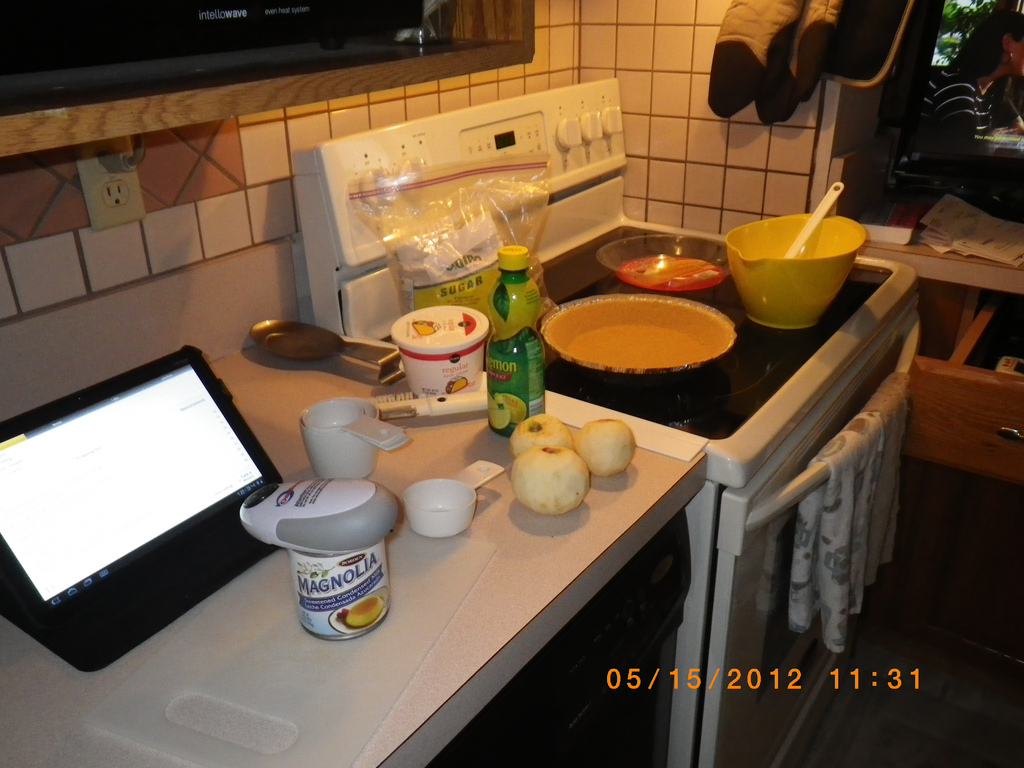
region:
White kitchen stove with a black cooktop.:
[286, 71, 917, 764]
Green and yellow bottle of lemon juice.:
[486, 242, 548, 440]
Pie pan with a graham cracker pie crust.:
[536, 286, 739, 388]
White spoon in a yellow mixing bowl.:
[722, 177, 866, 333]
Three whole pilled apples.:
[507, 403, 632, 517]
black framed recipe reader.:
[0, 342, 292, 669]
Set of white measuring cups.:
[294, 393, 502, 536]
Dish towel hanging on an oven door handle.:
[691, 285, 925, 764]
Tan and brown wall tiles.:
[0, 1, 823, 322]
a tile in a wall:
[0, 235, 93, 305]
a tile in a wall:
[75, 216, 148, 296]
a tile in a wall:
[136, 202, 220, 286]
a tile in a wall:
[176, 172, 265, 250]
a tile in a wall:
[240, 175, 299, 243]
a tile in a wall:
[234, 127, 308, 198]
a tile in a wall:
[266, 105, 330, 150]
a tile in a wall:
[325, 104, 384, 130]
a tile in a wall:
[359, 101, 399, 120]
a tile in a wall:
[417, 83, 490, 121]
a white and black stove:
[296, 91, 925, 766]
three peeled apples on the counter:
[501, 398, 657, 515]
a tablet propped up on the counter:
[13, 345, 308, 671]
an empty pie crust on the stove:
[537, 290, 738, 388]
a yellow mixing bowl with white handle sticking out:
[717, 196, 873, 321]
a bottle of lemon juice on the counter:
[480, 249, 551, 442]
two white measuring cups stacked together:
[287, 388, 414, 491]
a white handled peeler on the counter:
[372, 383, 509, 428]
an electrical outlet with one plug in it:
[68, 146, 166, 235]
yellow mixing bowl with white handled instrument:
[725, 180, 866, 330]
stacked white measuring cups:
[299, 398, 408, 476]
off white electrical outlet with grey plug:
[73, 132, 147, 230]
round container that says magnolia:
[291, 550, 387, 640]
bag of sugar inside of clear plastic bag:
[346, 154, 558, 364]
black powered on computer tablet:
[0, 345, 282, 672]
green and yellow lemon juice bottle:
[488, 246, 545, 437]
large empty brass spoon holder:
[250, 319, 405, 386]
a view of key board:
[72, 516, 237, 633]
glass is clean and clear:
[935, 3, 1000, 68]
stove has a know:
[581, 112, 604, 142]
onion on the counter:
[559, 415, 629, 470]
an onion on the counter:
[524, 457, 567, 514]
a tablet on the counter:
[70, 296, 309, 699]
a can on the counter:
[257, 497, 422, 701]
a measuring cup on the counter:
[323, 384, 412, 486]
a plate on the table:
[540, 245, 711, 420]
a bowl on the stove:
[625, 204, 701, 296]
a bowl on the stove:
[739, 179, 866, 342]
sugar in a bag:
[360, 105, 537, 311]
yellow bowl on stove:
[710, 203, 870, 339]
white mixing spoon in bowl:
[785, 168, 847, 254]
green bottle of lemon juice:
[488, 240, 542, 441]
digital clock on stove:
[485, 123, 525, 153]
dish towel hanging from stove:
[784, 411, 905, 661]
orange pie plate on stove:
[528, 281, 743, 387]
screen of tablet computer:
[2, 347, 262, 594]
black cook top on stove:
[531, 197, 898, 448]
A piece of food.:
[522, 434, 603, 521]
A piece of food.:
[575, 413, 653, 486]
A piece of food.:
[496, 402, 580, 460]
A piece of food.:
[518, 446, 591, 500]